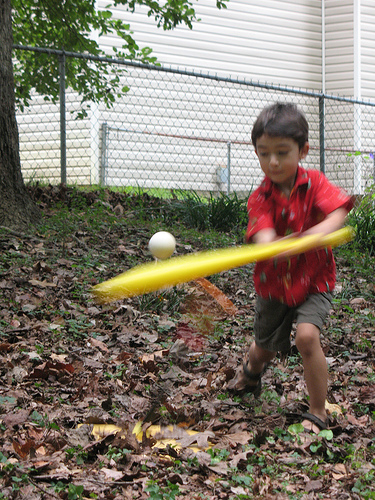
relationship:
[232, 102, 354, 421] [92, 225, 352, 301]
boy swinging bat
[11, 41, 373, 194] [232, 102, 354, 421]
fence behind boy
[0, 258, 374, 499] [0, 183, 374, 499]
leaves on ground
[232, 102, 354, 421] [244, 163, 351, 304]
boy wearing a shirt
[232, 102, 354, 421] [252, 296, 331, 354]
boy wearing shorts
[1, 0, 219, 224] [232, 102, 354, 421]
tree beside boy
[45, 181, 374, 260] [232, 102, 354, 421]
grass behind boy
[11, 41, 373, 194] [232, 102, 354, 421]
house behind boy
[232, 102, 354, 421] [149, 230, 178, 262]
boy hits a ball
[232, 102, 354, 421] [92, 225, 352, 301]
boy holds a bat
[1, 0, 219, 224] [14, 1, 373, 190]
tree in front of home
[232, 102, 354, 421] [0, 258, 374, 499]
boy in leaves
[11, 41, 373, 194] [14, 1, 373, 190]
fence near home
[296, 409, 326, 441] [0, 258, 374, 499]
sandal in leaves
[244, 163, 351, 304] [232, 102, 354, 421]
shirt on boy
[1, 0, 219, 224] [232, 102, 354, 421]
tree near boy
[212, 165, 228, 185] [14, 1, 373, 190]
box on home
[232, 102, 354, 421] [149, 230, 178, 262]
boy hitting a ball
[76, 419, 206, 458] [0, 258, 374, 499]
object in leaves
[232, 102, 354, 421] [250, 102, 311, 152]
boy has hair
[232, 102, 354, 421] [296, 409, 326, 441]
boy wearing a sandal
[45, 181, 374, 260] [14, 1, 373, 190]
grass next to home